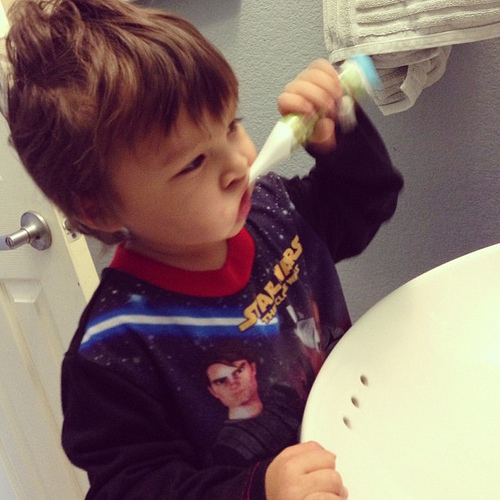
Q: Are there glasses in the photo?
A: No, there are no glasses.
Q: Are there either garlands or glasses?
A: No, there are no glasses or garlands.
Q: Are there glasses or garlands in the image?
A: No, there are no glasses or garlands.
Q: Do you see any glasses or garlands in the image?
A: No, there are no glasses or garlands.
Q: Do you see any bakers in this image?
A: No, there are no bakers.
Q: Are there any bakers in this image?
A: No, there are no bakers.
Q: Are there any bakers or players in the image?
A: No, there are no bakers or players.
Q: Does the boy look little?
A: Yes, the boy is little.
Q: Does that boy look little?
A: Yes, the boy is little.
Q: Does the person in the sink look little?
A: Yes, the boy is little.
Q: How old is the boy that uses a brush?
A: The boy is little.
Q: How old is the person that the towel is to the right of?
A: The boy is little.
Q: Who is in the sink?
A: The boy is in the sink.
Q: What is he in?
A: The boy is in the sink.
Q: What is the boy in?
A: The boy is in the sink.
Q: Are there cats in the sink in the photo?
A: No, there is a boy in the sink.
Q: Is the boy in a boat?
A: No, the boy is in the sink.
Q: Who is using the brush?
A: The boy is using the brush.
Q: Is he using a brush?
A: Yes, the boy is using a brush.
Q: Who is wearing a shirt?
A: The boy is wearing a shirt.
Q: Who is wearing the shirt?
A: The boy is wearing a shirt.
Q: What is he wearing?
A: The boy is wearing a shirt.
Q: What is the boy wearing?
A: The boy is wearing a shirt.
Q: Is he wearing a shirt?
A: Yes, the boy is wearing a shirt.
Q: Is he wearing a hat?
A: No, the boy is wearing a shirt.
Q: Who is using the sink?
A: The boy is using the sink.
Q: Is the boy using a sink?
A: Yes, the boy is using a sink.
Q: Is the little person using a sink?
A: Yes, the boy is using a sink.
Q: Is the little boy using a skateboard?
A: No, the boy is using a sink.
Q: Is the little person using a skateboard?
A: No, the boy is using a sink.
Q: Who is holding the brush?
A: The boy is holding the brush.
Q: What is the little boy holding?
A: The boy is holding the brush.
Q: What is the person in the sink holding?
A: The boy is holding the brush.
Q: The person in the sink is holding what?
A: The boy is holding the brush.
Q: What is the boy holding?
A: The boy is holding the brush.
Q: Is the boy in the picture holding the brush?
A: Yes, the boy is holding the brush.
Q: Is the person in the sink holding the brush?
A: Yes, the boy is holding the brush.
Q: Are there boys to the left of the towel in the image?
A: Yes, there is a boy to the left of the towel.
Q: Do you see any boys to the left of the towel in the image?
A: Yes, there is a boy to the left of the towel.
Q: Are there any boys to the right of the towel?
A: No, the boy is to the left of the towel.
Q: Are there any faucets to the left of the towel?
A: No, there is a boy to the left of the towel.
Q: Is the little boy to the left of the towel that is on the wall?
A: Yes, the boy is to the left of the towel.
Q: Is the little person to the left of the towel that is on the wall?
A: Yes, the boy is to the left of the towel.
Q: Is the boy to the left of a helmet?
A: No, the boy is to the left of the towel.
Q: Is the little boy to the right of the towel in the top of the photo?
A: No, the boy is to the left of the towel.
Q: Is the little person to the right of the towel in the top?
A: No, the boy is to the left of the towel.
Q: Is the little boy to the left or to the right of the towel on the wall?
A: The boy is to the left of the towel.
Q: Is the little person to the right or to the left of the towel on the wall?
A: The boy is to the left of the towel.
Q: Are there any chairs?
A: No, there are no chairs.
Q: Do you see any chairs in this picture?
A: No, there are no chairs.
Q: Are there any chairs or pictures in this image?
A: No, there are no chairs or pictures.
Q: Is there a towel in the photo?
A: Yes, there is a towel.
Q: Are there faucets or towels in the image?
A: Yes, there is a towel.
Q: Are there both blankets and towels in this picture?
A: No, there is a towel but no blankets.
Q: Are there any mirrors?
A: No, there are no mirrors.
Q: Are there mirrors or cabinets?
A: No, there are no mirrors or cabinets.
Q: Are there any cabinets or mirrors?
A: No, there are no mirrors or cabinets.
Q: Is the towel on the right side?
A: Yes, the towel is on the right of the image.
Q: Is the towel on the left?
A: No, the towel is on the right of the image.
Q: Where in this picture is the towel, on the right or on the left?
A: The towel is on the right of the image.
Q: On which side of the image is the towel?
A: The towel is on the right of the image.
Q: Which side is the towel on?
A: The towel is on the right of the image.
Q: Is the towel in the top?
A: Yes, the towel is in the top of the image.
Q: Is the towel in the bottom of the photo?
A: No, the towel is in the top of the image.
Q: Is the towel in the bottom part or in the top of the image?
A: The towel is in the top of the image.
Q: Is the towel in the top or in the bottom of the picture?
A: The towel is in the top of the image.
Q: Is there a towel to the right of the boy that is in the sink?
A: Yes, there is a towel to the right of the boy.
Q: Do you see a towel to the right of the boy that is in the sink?
A: Yes, there is a towel to the right of the boy.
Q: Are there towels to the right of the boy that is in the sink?
A: Yes, there is a towel to the right of the boy.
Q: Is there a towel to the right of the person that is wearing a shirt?
A: Yes, there is a towel to the right of the boy.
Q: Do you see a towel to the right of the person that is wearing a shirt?
A: Yes, there is a towel to the right of the boy.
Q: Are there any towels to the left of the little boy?
A: No, the towel is to the right of the boy.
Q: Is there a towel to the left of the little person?
A: No, the towel is to the right of the boy.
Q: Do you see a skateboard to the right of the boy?
A: No, there is a towel to the right of the boy.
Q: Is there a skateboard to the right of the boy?
A: No, there is a towel to the right of the boy.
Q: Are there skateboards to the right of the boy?
A: No, there is a towel to the right of the boy.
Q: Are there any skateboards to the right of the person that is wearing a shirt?
A: No, there is a towel to the right of the boy.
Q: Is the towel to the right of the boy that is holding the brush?
A: Yes, the towel is to the right of the boy.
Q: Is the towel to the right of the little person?
A: Yes, the towel is to the right of the boy.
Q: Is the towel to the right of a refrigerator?
A: No, the towel is to the right of the boy.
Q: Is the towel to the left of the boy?
A: No, the towel is to the right of the boy.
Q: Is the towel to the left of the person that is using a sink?
A: No, the towel is to the right of the boy.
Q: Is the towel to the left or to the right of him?
A: The towel is to the right of the boy.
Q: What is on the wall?
A: The towel is on the wall.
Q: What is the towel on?
A: The towel is on the wall.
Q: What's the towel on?
A: The towel is on the wall.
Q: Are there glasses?
A: No, there are no glasses.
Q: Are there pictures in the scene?
A: No, there are no pictures.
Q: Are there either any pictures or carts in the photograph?
A: No, there are no pictures or carts.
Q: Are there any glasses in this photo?
A: No, there are no glasses.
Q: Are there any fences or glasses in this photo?
A: No, there are no glasses or fences.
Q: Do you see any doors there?
A: Yes, there is a door.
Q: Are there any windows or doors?
A: Yes, there is a door.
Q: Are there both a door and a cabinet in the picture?
A: No, there is a door but no cabinets.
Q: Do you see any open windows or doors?
A: Yes, there is an open door.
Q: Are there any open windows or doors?
A: Yes, there is an open door.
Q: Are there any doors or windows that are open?
A: Yes, the door is open.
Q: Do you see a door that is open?
A: Yes, there is an open door.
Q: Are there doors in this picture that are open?
A: Yes, there is a door that is open.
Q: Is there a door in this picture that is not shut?
A: Yes, there is a open door.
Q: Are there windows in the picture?
A: No, there are no windows.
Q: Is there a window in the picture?
A: No, there are no windows.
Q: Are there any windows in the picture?
A: No, there are no windows.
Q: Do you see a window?
A: No, there are no windows.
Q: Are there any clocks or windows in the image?
A: No, there are no windows or clocks.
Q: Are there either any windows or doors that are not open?
A: No, there is a door but it is open.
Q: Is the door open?
A: Yes, the door is open.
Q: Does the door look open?
A: Yes, the door is open.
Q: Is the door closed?
A: No, the door is open.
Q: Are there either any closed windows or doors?
A: No, there is a door but it is open.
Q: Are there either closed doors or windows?
A: No, there is a door but it is open.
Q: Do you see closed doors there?
A: No, there is a door but it is open.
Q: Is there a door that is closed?
A: No, there is a door but it is open.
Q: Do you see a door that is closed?
A: No, there is a door but it is open.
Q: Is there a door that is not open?
A: No, there is a door but it is open.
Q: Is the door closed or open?
A: The door is open.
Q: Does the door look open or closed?
A: The door is open.